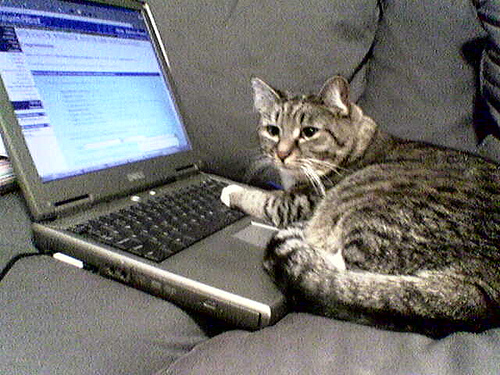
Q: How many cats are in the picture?
A: One.